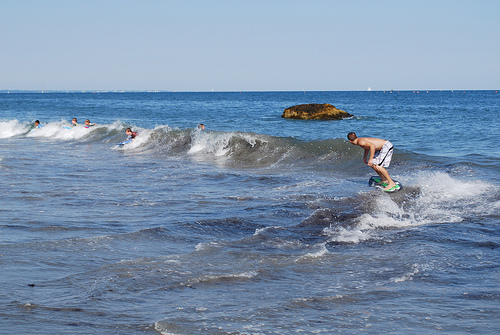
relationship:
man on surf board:
[346, 131, 397, 190] [364, 178, 404, 194]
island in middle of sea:
[282, 103, 352, 122] [0, 88, 494, 333]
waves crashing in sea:
[199, 130, 287, 173] [0, 90, 499, 334]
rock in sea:
[280, 101, 352, 123] [0, 90, 499, 334]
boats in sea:
[365, 86, 486, 94] [0, 90, 499, 334]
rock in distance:
[280, 101, 354, 122] [27, 16, 480, 136]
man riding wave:
[346, 131, 397, 190] [275, 130, 475, 242]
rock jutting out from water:
[280, 101, 354, 122] [15, 86, 485, 313]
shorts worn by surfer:
[367, 140, 396, 172] [340, 129, 399, 195]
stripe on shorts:
[372, 141, 401, 172] [369, 138, 393, 169]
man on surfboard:
[346, 131, 397, 190] [362, 174, 402, 195]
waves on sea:
[0, 113, 499, 305] [0, 88, 494, 333]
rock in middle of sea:
[280, 101, 354, 122] [0, 90, 499, 334]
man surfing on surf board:
[346, 131, 397, 190] [367, 173, 404, 193]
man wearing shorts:
[346, 123, 403, 192] [369, 134, 395, 172]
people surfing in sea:
[26, 111, 209, 140] [0, 90, 499, 334]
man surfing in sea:
[346, 131, 397, 190] [0, 90, 499, 334]